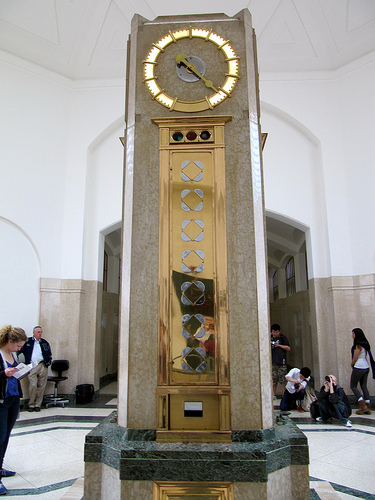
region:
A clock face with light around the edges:
[135, 26, 245, 118]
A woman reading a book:
[0, 324, 35, 447]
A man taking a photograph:
[308, 370, 353, 431]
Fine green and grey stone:
[81, 418, 312, 498]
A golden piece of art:
[150, 110, 230, 446]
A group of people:
[268, 319, 374, 418]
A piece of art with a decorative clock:
[81, 5, 309, 498]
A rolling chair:
[38, 354, 73, 409]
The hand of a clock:
[170, 47, 220, 110]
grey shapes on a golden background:
[174, 158, 208, 379]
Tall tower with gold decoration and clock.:
[83, 7, 309, 498]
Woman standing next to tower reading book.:
[0, 325, 42, 493]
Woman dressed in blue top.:
[1, 350, 17, 397]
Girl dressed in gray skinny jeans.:
[346, 366, 371, 402]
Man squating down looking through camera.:
[315, 367, 354, 431]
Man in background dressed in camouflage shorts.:
[270, 360, 288, 390]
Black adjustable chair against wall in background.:
[45, 355, 70, 411]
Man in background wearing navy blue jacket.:
[19, 334, 53, 365]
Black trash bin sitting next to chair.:
[75, 381, 98, 404]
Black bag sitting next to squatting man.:
[306, 397, 322, 422]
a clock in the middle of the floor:
[75, 8, 320, 498]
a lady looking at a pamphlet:
[1, 321, 33, 495]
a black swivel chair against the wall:
[49, 355, 73, 407]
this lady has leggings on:
[352, 326, 373, 425]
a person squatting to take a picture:
[305, 369, 358, 433]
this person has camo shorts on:
[270, 323, 287, 392]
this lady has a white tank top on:
[347, 343, 373, 371]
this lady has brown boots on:
[356, 394, 372, 415]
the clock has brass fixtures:
[153, 117, 249, 449]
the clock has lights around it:
[141, 24, 240, 111]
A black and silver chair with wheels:
[38, 354, 90, 422]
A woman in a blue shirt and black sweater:
[0, 325, 54, 457]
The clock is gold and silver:
[132, 16, 245, 118]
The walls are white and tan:
[312, 257, 369, 386]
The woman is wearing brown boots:
[348, 390, 372, 422]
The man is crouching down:
[305, 375, 361, 430]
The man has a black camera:
[309, 363, 354, 432]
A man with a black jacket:
[21, 324, 62, 408]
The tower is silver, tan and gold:
[73, 3, 318, 485]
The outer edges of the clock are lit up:
[145, 30, 256, 109]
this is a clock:
[141, 30, 235, 108]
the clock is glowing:
[141, 27, 241, 106]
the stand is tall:
[131, 10, 243, 440]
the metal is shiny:
[210, 211, 227, 242]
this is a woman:
[1, 324, 33, 400]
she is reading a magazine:
[4, 354, 37, 379]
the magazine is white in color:
[10, 360, 41, 377]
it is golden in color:
[210, 387, 226, 427]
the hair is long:
[0, 325, 21, 337]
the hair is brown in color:
[1, 325, 23, 340]